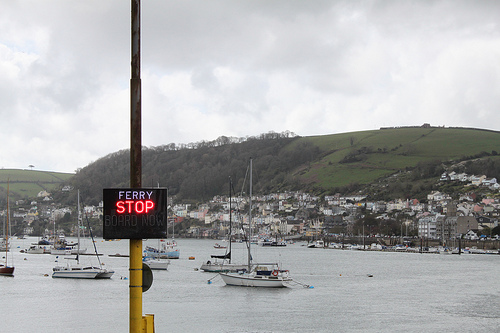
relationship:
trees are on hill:
[17, 129, 321, 206] [0, 127, 499, 211]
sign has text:
[102, 187, 167, 239] [115, 190, 155, 213]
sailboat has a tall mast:
[218, 158, 291, 288] [246, 157, 252, 272]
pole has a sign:
[129, 0, 143, 333] [102, 187, 167, 239]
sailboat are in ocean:
[52, 189, 114, 279] [1, 235, 499, 333]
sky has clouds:
[1, 1, 499, 174] [1, 1, 499, 174]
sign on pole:
[102, 187, 167, 239] [129, 0, 143, 333]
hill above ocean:
[0, 127, 499, 211] [1, 235, 499, 333]